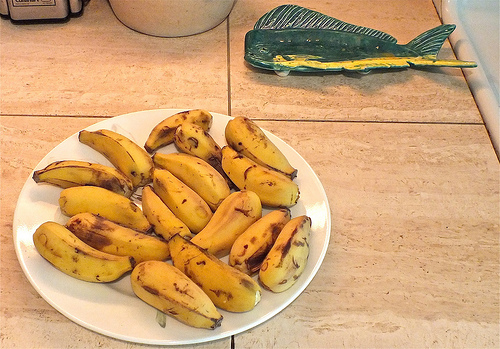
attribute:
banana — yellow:
[258, 212, 313, 292]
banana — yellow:
[78, 130, 162, 185]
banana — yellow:
[35, 221, 135, 285]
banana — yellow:
[149, 152, 234, 208]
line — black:
[241, 114, 484, 139]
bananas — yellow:
[32, 111, 316, 329]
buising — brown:
[86, 219, 104, 258]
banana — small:
[219, 142, 300, 209]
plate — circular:
[113, 102, 357, 226]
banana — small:
[193, 193, 254, 265]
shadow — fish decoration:
[253, 61, 468, 87]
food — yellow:
[25, 108, 311, 318]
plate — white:
[24, 265, 167, 346]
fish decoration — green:
[240, 3, 485, 79]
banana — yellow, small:
[131, 258, 223, 330]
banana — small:
[224, 208, 301, 274]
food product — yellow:
[14, 99, 326, 308]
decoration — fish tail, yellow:
[389, 11, 481, 72]